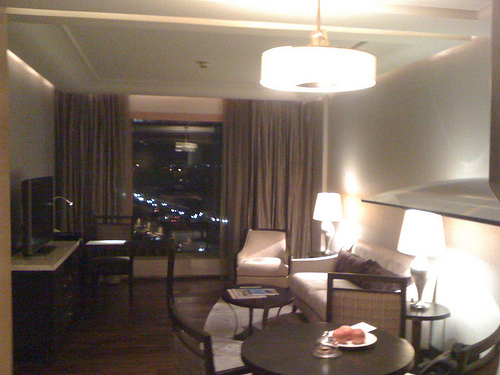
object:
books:
[247, 287, 277, 295]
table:
[223, 282, 297, 341]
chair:
[76, 214, 135, 304]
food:
[351, 335, 365, 345]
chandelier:
[258, 42, 379, 96]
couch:
[289, 239, 424, 323]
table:
[240, 320, 415, 375]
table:
[402, 302, 451, 361]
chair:
[324, 270, 409, 337]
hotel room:
[0, 0, 500, 375]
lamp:
[400, 210, 446, 315]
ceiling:
[6, 0, 490, 96]